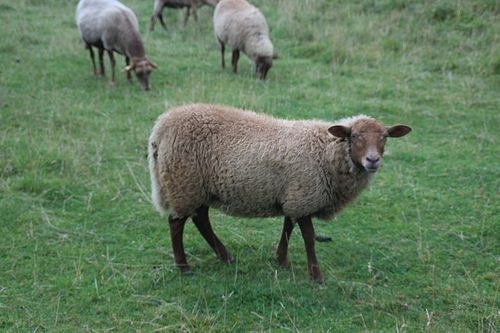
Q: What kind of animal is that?
A: A sheep.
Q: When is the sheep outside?
A: During the day.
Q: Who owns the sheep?
A: The shepherd.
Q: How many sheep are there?
A: 4.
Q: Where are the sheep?
A: In the pasture.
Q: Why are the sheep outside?
A: They are grazing.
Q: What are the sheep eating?
A: Grass.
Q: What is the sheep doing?
A: Eating grass.